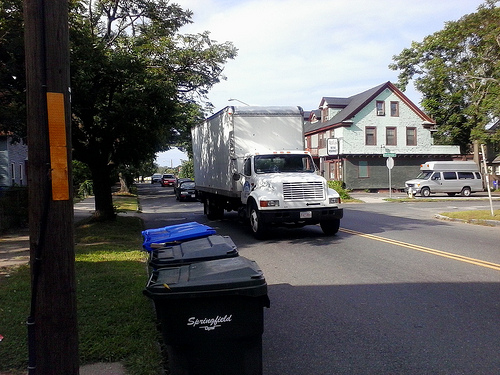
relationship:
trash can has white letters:
[142, 256, 270, 375] [180, 305, 238, 339]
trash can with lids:
[142, 256, 270, 375] [145, 255, 265, 293]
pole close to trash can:
[11, 2, 96, 374] [142, 256, 270, 375]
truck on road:
[178, 97, 356, 240] [264, 214, 492, 374]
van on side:
[400, 151, 493, 207] [340, 148, 497, 212]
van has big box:
[178, 97, 356, 240] [174, 89, 309, 163]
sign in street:
[378, 146, 401, 201] [132, 183, 500, 373]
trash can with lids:
[141, 221, 217, 253] [133, 212, 270, 308]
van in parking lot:
[400, 151, 493, 207] [349, 180, 499, 197]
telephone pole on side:
[11, 2, 96, 374] [6, 163, 138, 375]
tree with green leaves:
[1, 0, 224, 226] [0, 1, 233, 169]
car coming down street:
[172, 174, 203, 207] [139, 167, 201, 212]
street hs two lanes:
[146, 181, 491, 374] [341, 222, 498, 276]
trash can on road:
[142, 256, 270, 375] [264, 214, 492, 374]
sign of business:
[320, 132, 347, 163] [302, 78, 454, 186]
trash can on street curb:
[136, 254, 275, 375] [99, 181, 160, 372]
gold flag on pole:
[42, 83, 76, 207] [11, 2, 96, 374]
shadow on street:
[355, 195, 451, 253] [132, 183, 500, 373]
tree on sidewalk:
[1, 0, 224, 226] [6, 163, 138, 375]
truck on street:
[178, 97, 356, 240] [146, 181, 491, 374]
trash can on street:
[142, 256, 270, 375] [146, 181, 491, 374]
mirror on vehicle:
[231, 167, 245, 185] [178, 97, 356, 240]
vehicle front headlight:
[178, 97, 356, 240] [256, 194, 346, 213]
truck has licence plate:
[190, 105, 344, 239] [182, 99, 348, 239]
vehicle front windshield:
[178, 97, 356, 240] [248, 148, 318, 175]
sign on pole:
[378, 146, 401, 201] [385, 168, 396, 199]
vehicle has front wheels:
[178, 97, 356, 240] [243, 204, 350, 243]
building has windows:
[302, 78, 454, 186] [362, 99, 422, 154]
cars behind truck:
[139, 167, 201, 212] [188, 101, 343, 240]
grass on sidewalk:
[0, 191, 167, 372] [6, 163, 138, 375]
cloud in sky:
[177, 3, 478, 115] [191, 5, 440, 90]